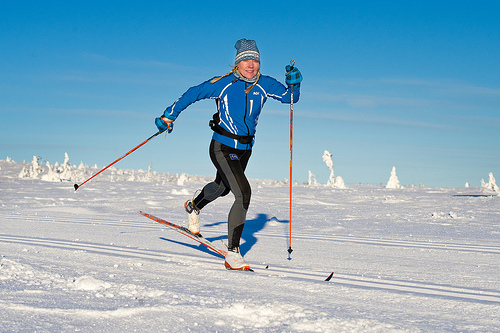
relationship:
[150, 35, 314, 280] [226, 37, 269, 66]
woman wearing beanie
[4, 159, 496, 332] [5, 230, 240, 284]
snow has tracks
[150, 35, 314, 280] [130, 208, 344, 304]
woman on skis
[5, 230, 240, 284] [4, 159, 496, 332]
tracks in snow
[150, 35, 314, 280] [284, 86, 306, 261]
woman holding pole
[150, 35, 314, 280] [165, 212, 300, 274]
woman has shadow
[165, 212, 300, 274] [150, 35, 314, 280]
shadow of woman